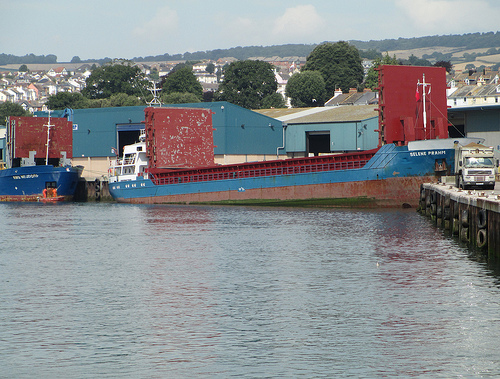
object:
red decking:
[148, 145, 381, 185]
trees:
[3, 32, 498, 62]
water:
[0, 193, 497, 379]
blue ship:
[106, 137, 484, 210]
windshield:
[464, 156, 494, 168]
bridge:
[416, 180, 499, 271]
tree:
[0, 100, 30, 126]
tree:
[46, 91, 86, 109]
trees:
[283, 68, 327, 105]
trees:
[301, 42, 363, 92]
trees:
[219, 59, 285, 109]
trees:
[159, 60, 204, 103]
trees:
[86, 65, 143, 96]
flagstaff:
[413, 73, 433, 140]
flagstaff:
[41, 112, 56, 167]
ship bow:
[409, 135, 489, 178]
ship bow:
[34, 165, 74, 202]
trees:
[85, 91, 160, 108]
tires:
[414, 184, 490, 251]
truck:
[454, 141, 500, 191]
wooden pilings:
[422, 176, 499, 258]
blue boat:
[0, 163, 84, 202]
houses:
[1, 68, 89, 107]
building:
[0, 99, 380, 181]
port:
[0, 109, 499, 378]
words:
[410, 150, 446, 157]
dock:
[417, 172, 500, 271]